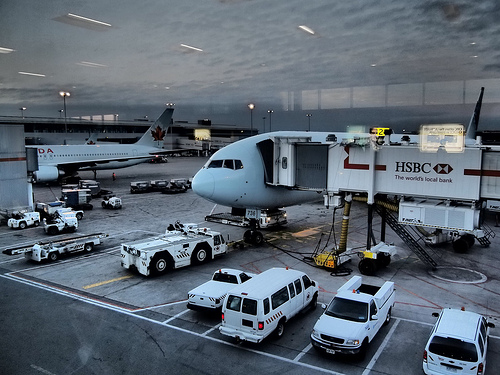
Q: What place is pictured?
A: It is an airport.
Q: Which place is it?
A: It is an airport.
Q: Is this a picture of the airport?
A: Yes, it is showing the airport.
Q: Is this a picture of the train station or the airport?
A: It is showing the airport.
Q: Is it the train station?
A: No, it is the airport.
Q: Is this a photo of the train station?
A: No, the picture is showing the airport.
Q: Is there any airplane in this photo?
A: Yes, there is an airplane.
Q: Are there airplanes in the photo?
A: Yes, there is an airplane.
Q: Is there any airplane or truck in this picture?
A: Yes, there is an airplane.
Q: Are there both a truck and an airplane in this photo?
A: Yes, there are both an airplane and a truck.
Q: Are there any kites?
A: No, there are no kites.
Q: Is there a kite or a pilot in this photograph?
A: No, there are no kites or pilots.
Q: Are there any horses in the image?
A: No, there are no horses.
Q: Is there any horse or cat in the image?
A: No, there are no horses or cats.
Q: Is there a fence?
A: No, there are no fences.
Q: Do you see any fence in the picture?
A: No, there are no fences.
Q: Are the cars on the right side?
A: Yes, the cars are on the right of the image.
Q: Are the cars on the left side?
A: No, the cars are on the right of the image.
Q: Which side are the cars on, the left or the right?
A: The cars are on the right of the image.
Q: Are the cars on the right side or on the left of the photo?
A: The cars are on the right of the image.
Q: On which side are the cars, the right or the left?
A: The cars are on the right of the image.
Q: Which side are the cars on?
A: The cars are on the right of the image.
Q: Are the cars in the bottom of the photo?
A: Yes, the cars are in the bottom of the image.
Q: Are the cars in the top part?
A: No, the cars are in the bottom of the image.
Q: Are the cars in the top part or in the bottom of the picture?
A: The cars are in the bottom of the image.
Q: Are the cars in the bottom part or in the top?
A: The cars are in the bottom of the image.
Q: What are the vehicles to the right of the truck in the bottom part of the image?
A: The vehicles are cars.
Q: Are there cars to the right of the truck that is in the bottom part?
A: Yes, there are cars to the right of the truck.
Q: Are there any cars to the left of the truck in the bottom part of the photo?
A: No, the cars are to the right of the truck.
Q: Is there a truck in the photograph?
A: Yes, there is a truck.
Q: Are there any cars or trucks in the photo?
A: Yes, there is a truck.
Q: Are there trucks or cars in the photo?
A: Yes, there is a truck.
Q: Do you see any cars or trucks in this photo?
A: Yes, there is a truck.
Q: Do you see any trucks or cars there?
A: Yes, there is a truck.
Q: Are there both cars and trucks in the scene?
A: Yes, there are both a truck and a car.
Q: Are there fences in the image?
A: No, there are no fences.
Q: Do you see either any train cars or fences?
A: No, there are no fences or train cars.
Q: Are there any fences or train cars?
A: No, there are no fences or train cars.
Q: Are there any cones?
A: No, there are no cones.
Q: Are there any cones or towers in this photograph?
A: No, there are no cones or towers.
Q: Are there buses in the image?
A: No, there are no buses.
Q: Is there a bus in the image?
A: No, there are no buses.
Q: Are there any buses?
A: No, there are no buses.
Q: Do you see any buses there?
A: No, there are no buses.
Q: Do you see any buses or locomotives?
A: No, there are no buses or locomotives.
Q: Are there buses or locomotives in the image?
A: No, there are no buses or locomotives.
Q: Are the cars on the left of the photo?
A: No, the cars are on the right of the image.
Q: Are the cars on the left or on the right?
A: The cars are on the right of the image.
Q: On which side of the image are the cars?
A: The cars are on the right of the image.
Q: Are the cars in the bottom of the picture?
A: Yes, the cars are in the bottom of the image.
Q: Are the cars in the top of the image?
A: No, the cars are in the bottom of the image.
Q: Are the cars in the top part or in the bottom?
A: The cars are in the bottom of the image.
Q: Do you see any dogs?
A: No, there are no dogs.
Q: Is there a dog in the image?
A: No, there are no dogs.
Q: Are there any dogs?
A: No, there are no dogs.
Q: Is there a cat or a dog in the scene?
A: No, there are no dogs or cats.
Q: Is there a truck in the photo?
A: Yes, there is a truck.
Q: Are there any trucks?
A: Yes, there is a truck.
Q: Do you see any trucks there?
A: Yes, there is a truck.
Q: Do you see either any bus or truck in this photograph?
A: Yes, there is a truck.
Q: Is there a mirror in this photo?
A: No, there are no mirrors.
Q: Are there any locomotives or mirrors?
A: No, there are no mirrors or locomotives.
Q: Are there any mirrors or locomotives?
A: No, there are no mirrors or locomotives.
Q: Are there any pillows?
A: No, there are no pillows.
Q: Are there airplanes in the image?
A: Yes, there is an airplane.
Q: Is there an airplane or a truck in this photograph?
A: Yes, there is an airplane.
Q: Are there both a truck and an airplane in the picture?
A: Yes, there are both an airplane and a truck.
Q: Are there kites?
A: No, there are no kites.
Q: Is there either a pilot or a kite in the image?
A: No, there are no kites or pilots.